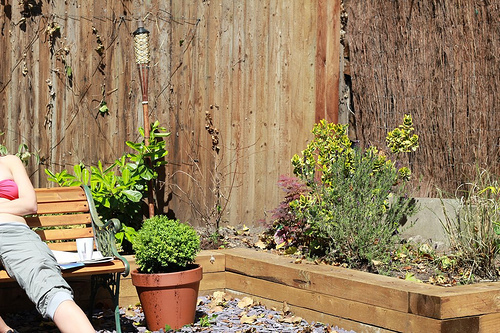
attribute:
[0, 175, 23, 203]
top — pink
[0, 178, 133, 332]
bench — wood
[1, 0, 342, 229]
fence — wood, wooden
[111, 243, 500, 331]
planters — wood